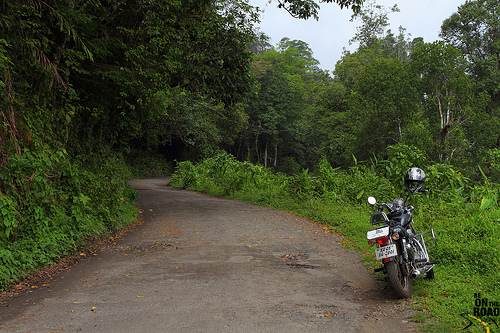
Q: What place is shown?
A: It is a park.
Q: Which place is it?
A: It is a park.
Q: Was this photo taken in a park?
A: Yes, it was taken in a park.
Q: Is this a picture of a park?
A: Yes, it is showing a park.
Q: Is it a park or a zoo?
A: It is a park.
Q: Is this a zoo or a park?
A: It is a park.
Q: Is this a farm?
A: No, it is a park.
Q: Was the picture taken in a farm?
A: No, the picture was taken in a park.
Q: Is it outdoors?
A: Yes, it is outdoors.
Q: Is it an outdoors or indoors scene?
A: It is outdoors.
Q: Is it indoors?
A: No, it is outdoors.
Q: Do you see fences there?
A: No, there are no fences.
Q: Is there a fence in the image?
A: No, there are no fences.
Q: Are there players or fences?
A: No, there are no fences or players.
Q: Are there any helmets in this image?
A: Yes, there is a helmet.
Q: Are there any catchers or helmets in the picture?
A: Yes, there is a helmet.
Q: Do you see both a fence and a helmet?
A: No, there is a helmet but no fences.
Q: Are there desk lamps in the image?
A: No, there are no desk lamps.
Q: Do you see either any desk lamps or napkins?
A: No, there are no desk lamps or napkins.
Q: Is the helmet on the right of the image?
A: Yes, the helmet is on the right of the image.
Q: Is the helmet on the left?
A: No, the helmet is on the right of the image.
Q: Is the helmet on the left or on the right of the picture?
A: The helmet is on the right of the image.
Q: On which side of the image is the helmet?
A: The helmet is on the right of the image.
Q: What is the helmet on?
A: The helmet is on the motorbike.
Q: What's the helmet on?
A: The helmet is on the motorbike.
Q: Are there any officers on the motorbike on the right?
A: No, there is a helmet on the motorbike.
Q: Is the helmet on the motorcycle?
A: Yes, the helmet is on the motorcycle.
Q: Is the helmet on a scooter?
A: No, the helmet is on the motorcycle.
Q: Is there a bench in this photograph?
A: No, there are no benches.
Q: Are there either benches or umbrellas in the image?
A: No, there are no benches or umbrellas.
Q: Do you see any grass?
A: Yes, there is grass.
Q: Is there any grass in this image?
A: Yes, there is grass.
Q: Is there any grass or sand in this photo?
A: Yes, there is grass.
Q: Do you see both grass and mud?
A: No, there is grass but no mud.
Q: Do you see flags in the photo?
A: No, there are no flags.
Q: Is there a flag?
A: No, there are no flags.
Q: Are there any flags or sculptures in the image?
A: No, there are no flags or sculptures.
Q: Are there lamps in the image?
A: No, there are no lamps.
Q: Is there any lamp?
A: No, there are no lamps.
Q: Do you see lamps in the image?
A: No, there are no lamps.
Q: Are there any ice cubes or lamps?
A: No, there are no lamps or ice cubes.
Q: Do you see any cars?
A: No, there are no cars.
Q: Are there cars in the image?
A: No, there are no cars.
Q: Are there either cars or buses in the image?
A: No, there are no cars or buses.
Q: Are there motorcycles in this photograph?
A: Yes, there is a motorcycle.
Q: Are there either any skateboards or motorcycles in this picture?
A: Yes, there is a motorcycle.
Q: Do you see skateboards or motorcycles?
A: Yes, there is a motorcycle.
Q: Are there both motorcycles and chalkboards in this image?
A: No, there is a motorcycle but no chalkboards.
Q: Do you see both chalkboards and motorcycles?
A: No, there is a motorcycle but no chalkboards.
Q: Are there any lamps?
A: No, there are no lamps.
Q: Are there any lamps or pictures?
A: No, there are no lamps or pictures.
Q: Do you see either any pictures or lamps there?
A: No, there are no lamps or pictures.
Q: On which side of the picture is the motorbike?
A: The motorbike is on the right of the image.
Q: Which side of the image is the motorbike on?
A: The motorbike is on the right of the image.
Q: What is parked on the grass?
A: The motorcycle is parked on the grass.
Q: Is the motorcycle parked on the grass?
A: Yes, the motorcycle is parked on the grass.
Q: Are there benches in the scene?
A: No, there are no benches.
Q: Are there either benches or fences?
A: No, there are no benches or fences.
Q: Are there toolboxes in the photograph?
A: No, there are no toolboxes.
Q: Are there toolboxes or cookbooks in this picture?
A: No, there are no toolboxes or cookbooks.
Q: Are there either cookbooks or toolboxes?
A: No, there are no toolboxes or cookbooks.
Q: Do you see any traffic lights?
A: No, there are no traffic lights.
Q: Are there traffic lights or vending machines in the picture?
A: No, there are no traffic lights or vending machines.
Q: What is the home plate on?
A: The home plate is on the motorcycle.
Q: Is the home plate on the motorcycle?
A: Yes, the home plate is on the motorcycle.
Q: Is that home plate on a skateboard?
A: No, the home plate is on the motorcycle.